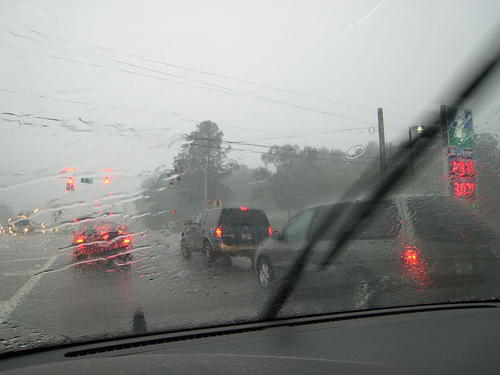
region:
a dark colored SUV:
[177, 205, 272, 268]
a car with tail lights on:
[71, 220, 131, 267]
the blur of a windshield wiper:
[244, 47, 497, 324]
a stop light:
[62, 173, 75, 193]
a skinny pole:
[376, 105, 388, 199]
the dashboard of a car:
[0, 297, 499, 374]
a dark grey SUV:
[253, 192, 498, 309]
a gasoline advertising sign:
[437, 101, 479, 212]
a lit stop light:
[100, 173, 107, 185]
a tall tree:
[170, 118, 233, 215]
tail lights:
[62, 209, 142, 269]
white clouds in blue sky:
[40, 13, 97, 64]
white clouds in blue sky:
[252, 51, 309, 96]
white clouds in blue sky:
[307, 29, 417, 120]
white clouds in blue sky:
[147, 65, 185, 112]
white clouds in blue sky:
[80, 33, 137, 100]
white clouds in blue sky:
[160, 33, 220, 110]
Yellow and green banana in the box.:
[33, 353, 297, 370]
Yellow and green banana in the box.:
[210, 123, 454, 126]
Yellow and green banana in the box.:
[183, 82, 197, 334]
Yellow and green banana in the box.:
[23, 90, 262, 109]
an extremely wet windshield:
[2, 4, 498, 361]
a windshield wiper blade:
[246, 25, 498, 328]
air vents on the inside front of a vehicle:
[62, 294, 497, 361]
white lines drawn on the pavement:
[2, 251, 63, 323]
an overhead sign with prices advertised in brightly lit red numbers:
[444, 153, 481, 201]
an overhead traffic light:
[58, 170, 83, 192]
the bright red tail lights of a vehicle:
[66, 232, 136, 252]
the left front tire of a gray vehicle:
[242, 248, 282, 296]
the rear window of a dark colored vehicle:
[216, 208, 270, 230]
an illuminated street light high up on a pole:
[407, 123, 426, 138]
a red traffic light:
[39, 116, 126, 186]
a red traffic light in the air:
[62, 169, 107, 200]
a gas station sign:
[430, 89, 490, 234]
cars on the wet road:
[58, 66, 478, 317]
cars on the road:
[36, 109, 467, 374]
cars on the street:
[32, 176, 361, 374]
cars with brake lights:
[82, 155, 397, 315]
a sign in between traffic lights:
[59, 131, 129, 198]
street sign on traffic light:
[53, 161, 112, 190]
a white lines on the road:
[16, 226, 119, 367]